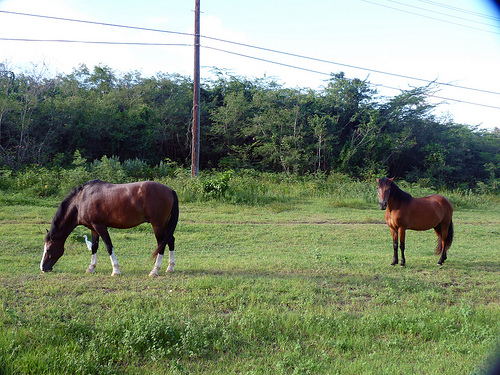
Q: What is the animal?
A: Horse.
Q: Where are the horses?
A: A field.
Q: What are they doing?
A: Eating.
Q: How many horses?
A: Two.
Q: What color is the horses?
A: Brown.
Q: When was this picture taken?
A: During the day.